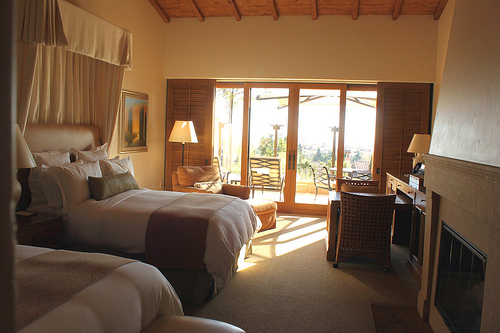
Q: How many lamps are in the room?
A: Three.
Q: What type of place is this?
A: Hotel.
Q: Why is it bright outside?
A: Sun is up.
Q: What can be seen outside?
A: Chairs.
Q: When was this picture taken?
A: Daytime.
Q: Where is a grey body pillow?
A: Bed.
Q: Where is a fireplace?
A: In wall bottom right.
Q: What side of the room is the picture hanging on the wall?
A: Left.